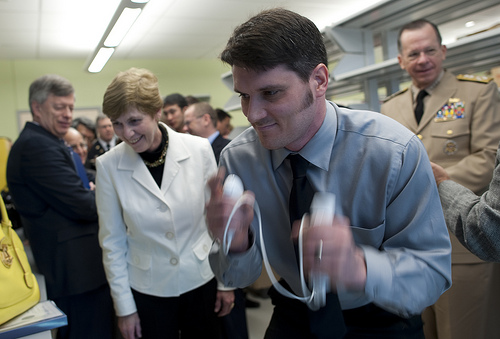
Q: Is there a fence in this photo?
A: No, there are no fences.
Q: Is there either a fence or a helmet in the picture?
A: No, there are no fences or helmets.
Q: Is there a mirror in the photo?
A: No, there are no mirrors.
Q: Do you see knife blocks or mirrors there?
A: No, there are no mirrors or knife blocks.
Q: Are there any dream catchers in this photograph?
A: No, there are no dream catchers.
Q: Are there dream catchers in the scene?
A: No, there are no dream catchers.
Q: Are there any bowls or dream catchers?
A: No, there are no dream catchers or bowls.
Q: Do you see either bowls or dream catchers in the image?
A: No, there are no dream catchers or bowls.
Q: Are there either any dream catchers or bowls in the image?
A: No, there are no dream catchers or bowls.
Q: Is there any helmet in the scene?
A: No, there are no helmets.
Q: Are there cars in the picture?
A: No, there are no cars.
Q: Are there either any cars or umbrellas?
A: No, there are no cars or umbrellas.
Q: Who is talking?
A: The people are talking.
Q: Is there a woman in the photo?
A: Yes, there is a woman.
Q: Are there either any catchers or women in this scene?
A: Yes, there is a woman.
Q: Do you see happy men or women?
A: Yes, there is a happy woman.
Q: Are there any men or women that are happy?
A: Yes, the woman is happy.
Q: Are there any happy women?
A: Yes, there is a happy woman.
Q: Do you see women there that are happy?
A: Yes, there is a woman that is happy.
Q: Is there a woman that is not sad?
A: Yes, there is a happy woman.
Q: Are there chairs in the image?
A: No, there are no chairs.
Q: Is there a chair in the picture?
A: No, there are no chairs.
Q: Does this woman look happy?
A: Yes, the woman is happy.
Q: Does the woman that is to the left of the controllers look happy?
A: Yes, the woman is happy.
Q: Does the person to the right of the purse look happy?
A: Yes, the woman is happy.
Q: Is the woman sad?
A: No, the woman is happy.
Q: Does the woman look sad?
A: No, the woman is happy.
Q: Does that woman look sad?
A: No, the woman is happy.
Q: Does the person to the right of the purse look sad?
A: No, the woman is happy.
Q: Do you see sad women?
A: No, there is a woman but she is happy.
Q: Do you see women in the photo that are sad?
A: No, there is a woman but she is happy.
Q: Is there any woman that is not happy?
A: No, there is a woman but she is happy.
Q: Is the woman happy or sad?
A: The woman is happy.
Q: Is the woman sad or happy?
A: The woman is happy.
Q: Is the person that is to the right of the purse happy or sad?
A: The woman is happy.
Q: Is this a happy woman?
A: Yes, this is a happy woman.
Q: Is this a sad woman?
A: No, this is a happy woman.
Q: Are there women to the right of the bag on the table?
A: Yes, there is a woman to the right of the purse.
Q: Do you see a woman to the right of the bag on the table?
A: Yes, there is a woman to the right of the purse.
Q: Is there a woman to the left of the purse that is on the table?
A: No, the woman is to the right of the purse.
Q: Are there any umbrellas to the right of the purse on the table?
A: No, there is a woman to the right of the purse.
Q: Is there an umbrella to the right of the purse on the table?
A: No, there is a woman to the right of the purse.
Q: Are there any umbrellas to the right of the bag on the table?
A: No, there is a woman to the right of the purse.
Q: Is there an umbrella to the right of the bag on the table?
A: No, there is a woman to the right of the purse.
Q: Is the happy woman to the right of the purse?
A: Yes, the woman is to the right of the purse.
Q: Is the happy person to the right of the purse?
A: Yes, the woman is to the right of the purse.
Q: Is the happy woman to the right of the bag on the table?
A: Yes, the woman is to the right of the purse.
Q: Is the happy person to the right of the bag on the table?
A: Yes, the woman is to the right of the purse.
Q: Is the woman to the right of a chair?
A: No, the woman is to the right of the purse.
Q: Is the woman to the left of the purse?
A: No, the woman is to the right of the purse.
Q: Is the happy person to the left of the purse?
A: No, the woman is to the right of the purse.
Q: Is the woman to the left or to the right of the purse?
A: The woman is to the right of the purse.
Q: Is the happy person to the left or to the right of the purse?
A: The woman is to the right of the purse.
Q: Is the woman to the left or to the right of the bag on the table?
A: The woman is to the right of the purse.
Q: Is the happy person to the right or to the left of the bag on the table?
A: The woman is to the right of the purse.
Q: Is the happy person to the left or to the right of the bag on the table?
A: The woman is to the right of the purse.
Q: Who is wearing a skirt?
A: The woman is wearing a skirt.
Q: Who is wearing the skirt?
A: The woman is wearing a skirt.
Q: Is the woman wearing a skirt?
A: Yes, the woman is wearing a skirt.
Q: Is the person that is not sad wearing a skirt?
A: Yes, the woman is wearing a skirt.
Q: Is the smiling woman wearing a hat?
A: No, the woman is wearing a skirt.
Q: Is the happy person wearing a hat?
A: No, the woman is wearing a skirt.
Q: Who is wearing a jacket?
A: The woman is wearing a jacket.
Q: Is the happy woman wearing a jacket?
A: Yes, the woman is wearing a jacket.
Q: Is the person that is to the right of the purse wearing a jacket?
A: Yes, the woman is wearing a jacket.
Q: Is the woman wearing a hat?
A: No, the woman is wearing a jacket.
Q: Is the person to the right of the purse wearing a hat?
A: No, the woman is wearing a jacket.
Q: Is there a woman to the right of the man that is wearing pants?
A: Yes, there is a woman to the right of the man.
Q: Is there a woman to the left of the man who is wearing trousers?
A: No, the woman is to the right of the man.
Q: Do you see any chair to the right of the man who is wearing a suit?
A: No, there is a woman to the right of the man.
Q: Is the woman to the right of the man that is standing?
A: Yes, the woman is to the right of the man.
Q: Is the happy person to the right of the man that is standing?
A: Yes, the woman is to the right of the man.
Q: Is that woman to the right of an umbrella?
A: No, the woman is to the right of the man.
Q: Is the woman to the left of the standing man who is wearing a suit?
A: No, the woman is to the right of the man.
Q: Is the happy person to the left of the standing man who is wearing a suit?
A: No, the woman is to the right of the man.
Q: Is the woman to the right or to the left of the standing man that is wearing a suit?
A: The woman is to the right of the man.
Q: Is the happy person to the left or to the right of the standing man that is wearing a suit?
A: The woman is to the right of the man.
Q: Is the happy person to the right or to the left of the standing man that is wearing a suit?
A: The woman is to the right of the man.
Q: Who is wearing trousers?
A: The woman is wearing trousers.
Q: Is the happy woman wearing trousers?
A: Yes, the woman is wearing trousers.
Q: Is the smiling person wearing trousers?
A: Yes, the woman is wearing trousers.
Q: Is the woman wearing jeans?
A: No, the woman is wearing trousers.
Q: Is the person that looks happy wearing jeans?
A: No, the woman is wearing trousers.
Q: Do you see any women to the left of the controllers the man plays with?
A: Yes, there is a woman to the left of the controllers.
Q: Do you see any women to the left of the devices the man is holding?
A: Yes, there is a woman to the left of the controllers.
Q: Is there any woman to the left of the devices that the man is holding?
A: Yes, there is a woman to the left of the controllers.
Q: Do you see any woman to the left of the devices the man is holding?
A: Yes, there is a woman to the left of the controllers.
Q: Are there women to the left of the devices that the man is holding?
A: Yes, there is a woman to the left of the controllers.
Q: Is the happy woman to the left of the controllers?
A: Yes, the woman is to the left of the controllers.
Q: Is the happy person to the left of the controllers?
A: Yes, the woman is to the left of the controllers.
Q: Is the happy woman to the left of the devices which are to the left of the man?
A: Yes, the woman is to the left of the controllers.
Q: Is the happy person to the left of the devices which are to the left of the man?
A: Yes, the woman is to the left of the controllers.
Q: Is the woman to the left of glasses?
A: No, the woman is to the left of the controllers.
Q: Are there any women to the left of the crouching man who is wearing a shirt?
A: Yes, there is a woman to the left of the man.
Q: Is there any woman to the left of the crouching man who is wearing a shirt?
A: Yes, there is a woman to the left of the man.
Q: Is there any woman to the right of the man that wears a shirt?
A: No, the woman is to the left of the man.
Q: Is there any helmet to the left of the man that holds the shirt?
A: No, there is a woman to the left of the man.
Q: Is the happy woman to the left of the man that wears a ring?
A: Yes, the woman is to the left of the man.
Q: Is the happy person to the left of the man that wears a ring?
A: Yes, the woman is to the left of the man.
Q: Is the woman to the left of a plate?
A: No, the woman is to the left of the man.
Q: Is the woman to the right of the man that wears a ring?
A: No, the woman is to the left of the man.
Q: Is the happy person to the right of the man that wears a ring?
A: No, the woman is to the left of the man.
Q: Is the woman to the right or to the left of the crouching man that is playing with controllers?
A: The woman is to the left of the man.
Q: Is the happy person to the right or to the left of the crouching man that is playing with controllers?
A: The woman is to the left of the man.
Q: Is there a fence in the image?
A: No, there are no fences.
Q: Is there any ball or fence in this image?
A: No, there are no fences or balls.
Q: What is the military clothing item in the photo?
A: The clothing item is a uniform.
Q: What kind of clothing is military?
A: The clothing is a uniform.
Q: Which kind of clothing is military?
A: The clothing is a uniform.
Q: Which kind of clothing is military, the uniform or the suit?
A: The uniform is military.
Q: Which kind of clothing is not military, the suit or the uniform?
A: The suit is not military.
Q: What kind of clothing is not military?
A: The clothing is a suit.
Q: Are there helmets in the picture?
A: No, there are no helmets.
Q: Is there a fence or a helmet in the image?
A: No, there are no helmets or fences.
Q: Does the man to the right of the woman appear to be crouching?
A: Yes, the man is crouching.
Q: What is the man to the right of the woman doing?
A: The man is crouching.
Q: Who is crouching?
A: The man is crouching.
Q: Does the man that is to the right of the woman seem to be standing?
A: No, the man is crouching.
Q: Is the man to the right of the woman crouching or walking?
A: The man is crouching.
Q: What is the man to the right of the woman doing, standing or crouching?
A: The man is crouching.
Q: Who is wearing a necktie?
A: The man is wearing a necktie.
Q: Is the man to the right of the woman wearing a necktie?
A: Yes, the man is wearing a necktie.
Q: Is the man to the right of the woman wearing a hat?
A: No, the man is wearing a necktie.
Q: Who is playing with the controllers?
A: The man is playing with the controllers.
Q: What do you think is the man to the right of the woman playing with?
A: The man is playing with controllers.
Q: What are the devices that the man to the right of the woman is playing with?
A: The devices are controllers.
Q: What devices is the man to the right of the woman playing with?
A: The man is playing with controllers.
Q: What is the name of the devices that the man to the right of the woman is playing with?
A: The devices are controllers.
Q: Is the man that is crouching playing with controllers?
A: Yes, the man is playing with controllers.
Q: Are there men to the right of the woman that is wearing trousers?
A: Yes, there is a man to the right of the woman.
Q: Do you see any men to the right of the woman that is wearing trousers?
A: Yes, there is a man to the right of the woman.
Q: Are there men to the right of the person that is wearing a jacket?
A: Yes, there is a man to the right of the woman.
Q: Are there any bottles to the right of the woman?
A: No, there is a man to the right of the woman.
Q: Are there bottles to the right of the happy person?
A: No, there is a man to the right of the woman.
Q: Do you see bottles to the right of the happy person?
A: No, there is a man to the right of the woman.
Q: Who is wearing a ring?
A: The man is wearing a ring.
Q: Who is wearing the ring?
A: The man is wearing a ring.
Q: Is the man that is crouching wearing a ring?
A: Yes, the man is wearing a ring.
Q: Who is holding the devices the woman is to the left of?
A: The man is holding the controllers.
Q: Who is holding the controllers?
A: The man is holding the controllers.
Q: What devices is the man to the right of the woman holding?
A: The man is holding the controllers.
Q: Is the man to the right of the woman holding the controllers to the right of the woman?
A: Yes, the man is holding the controllers.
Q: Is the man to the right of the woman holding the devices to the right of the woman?
A: Yes, the man is holding the controllers.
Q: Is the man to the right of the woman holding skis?
A: No, the man is holding the controllers.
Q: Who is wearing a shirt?
A: The man is wearing a shirt.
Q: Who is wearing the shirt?
A: The man is wearing a shirt.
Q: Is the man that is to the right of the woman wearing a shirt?
A: Yes, the man is wearing a shirt.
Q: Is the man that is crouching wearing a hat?
A: No, the man is wearing a shirt.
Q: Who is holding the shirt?
A: The man is holding the shirt.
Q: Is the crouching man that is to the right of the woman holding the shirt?
A: Yes, the man is holding the shirt.